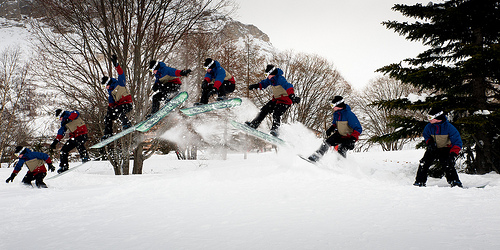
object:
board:
[180, 97, 243, 116]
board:
[296, 153, 349, 172]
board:
[230, 119, 288, 148]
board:
[134, 91, 189, 133]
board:
[89, 121, 145, 148]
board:
[44, 155, 103, 181]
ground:
[387, 87, 407, 120]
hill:
[1, 93, 481, 249]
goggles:
[425, 111, 443, 121]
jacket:
[422, 117, 464, 156]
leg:
[308, 132, 343, 162]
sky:
[15, 4, 493, 161]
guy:
[100, 54, 134, 140]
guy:
[412, 110, 463, 189]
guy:
[307, 96, 363, 167]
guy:
[247, 64, 302, 137]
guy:
[145, 58, 194, 120]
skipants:
[150, 83, 181, 114]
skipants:
[199, 80, 235, 104]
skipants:
[251, 100, 291, 131]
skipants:
[307, 130, 356, 162]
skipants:
[413, 146, 464, 187]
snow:
[0, 97, 499, 250]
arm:
[116, 66, 126, 86]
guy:
[193, 57, 237, 105]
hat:
[428, 108, 448, 120]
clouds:
[262, 8, 314, 56]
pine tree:
[363, 0, 500, 174]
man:
[49, 108, 89, 173]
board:
[462, 181, 491, 189]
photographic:
[0, 0, 500, 250]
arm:
[260, 77, 277, 88]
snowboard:
[23, 182, 50, 189]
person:
[5, 146, 56, 189]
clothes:
[12, 148, 54, 189]